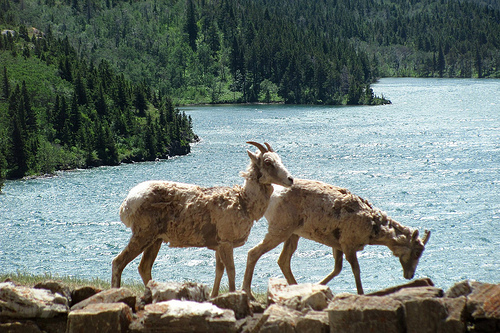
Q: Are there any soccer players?
A: No, there are no soccer players.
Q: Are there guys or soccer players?
A: No, there are no soccer players or guys.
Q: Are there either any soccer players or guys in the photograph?
A: No, there are no soccer players or guys.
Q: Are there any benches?
A: No, there are no benches.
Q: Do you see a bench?
A: No, there are no benches.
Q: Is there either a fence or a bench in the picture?
A: No, there are no benches or fences.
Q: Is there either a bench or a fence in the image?
A: No, there are no benches or fences.